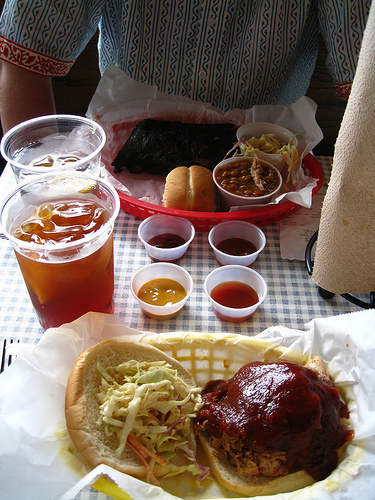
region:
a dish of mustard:
[129, 259, 194, 320]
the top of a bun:
[60, 336, 203, 484]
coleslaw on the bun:
[88, 354, 213, 492]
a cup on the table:
[0, 169, 122, 331]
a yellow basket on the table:
[52, 330, 372, 498]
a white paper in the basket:
[0, 305, 374, 498]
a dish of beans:
[210, 155, 283, 205]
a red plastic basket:
[83, 108, 328, 228]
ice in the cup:
[14, 197, 107, 255]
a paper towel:
[303, 0, 373, 300]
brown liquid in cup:
[24, 190, 157, 342]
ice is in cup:
[21, 184, 115, 259]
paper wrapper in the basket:
[0, 293, 372, 490]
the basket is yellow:
[44, 314, 363, 485]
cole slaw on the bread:
[84, 354, 201, 461]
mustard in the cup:
[134, 263, 198, 316]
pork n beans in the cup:
[208, 150, 293, 213]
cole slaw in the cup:
[232, 123, 302, 179]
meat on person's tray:
[107, 104, 278, 188]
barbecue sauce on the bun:
[212, 356, 334, 487]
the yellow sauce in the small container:
[129, 264, 189, 315]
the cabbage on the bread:
[105, 372, 184, 437]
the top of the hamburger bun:
[65, 338, 199, 474]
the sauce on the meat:
[225, 373, 297, 428]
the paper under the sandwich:
[323, 313, 373, 382]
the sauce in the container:
[204, 266, 264, 318]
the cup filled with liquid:
[0, 173, 123, 340]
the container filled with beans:
[212, 158, 282, 202]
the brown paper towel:
[306, 16, 374, 323]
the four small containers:
[127, 217, 271, 322]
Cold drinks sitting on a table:
[4, 111, 119, 326]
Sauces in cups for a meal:
[125, 210, 267, 325]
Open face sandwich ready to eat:
[56, 325, 356, 497]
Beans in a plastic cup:
[211, 150, 284, 202]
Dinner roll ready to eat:
[161, 162, 216, 212]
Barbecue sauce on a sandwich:
[201, 352, 360, 493]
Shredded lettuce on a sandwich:
[60, 335, 202, 485]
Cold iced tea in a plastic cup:
[0, 176, 121, 326]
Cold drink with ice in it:
[0, 172, 120, 338]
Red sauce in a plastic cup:
[201, 262, 271, 322]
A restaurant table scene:
[5, 57, 369, 489]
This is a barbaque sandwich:
[201, 356, 344, 489]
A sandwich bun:
[71, 337, 205, 478]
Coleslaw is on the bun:
[97, 358, 197, 466]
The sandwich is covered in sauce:
[222, 360, 324, 469]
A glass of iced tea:
[2, 169, 123, 328]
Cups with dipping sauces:
[129, 211, 272, 328]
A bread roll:
[162, 162, 216, 214]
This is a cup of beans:
[212, 154, 287, 202]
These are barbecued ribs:
[112, 115, 239, 170]